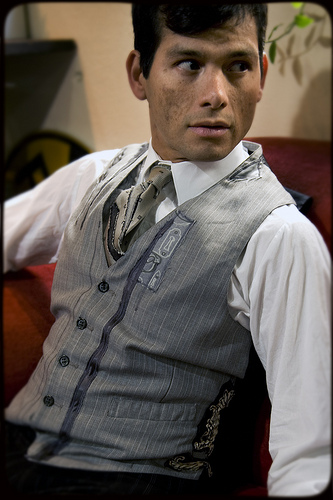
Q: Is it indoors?
A: Yes, it is indoors.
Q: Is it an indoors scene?
A: Yes, it is indoors.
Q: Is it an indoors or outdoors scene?
A: It is indoors.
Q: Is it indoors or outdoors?
A: It is indoors.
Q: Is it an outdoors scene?
A: No, it is indoors.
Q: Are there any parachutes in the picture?
A: No, there are no parachutes.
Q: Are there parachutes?
A: No, there are no parachutes.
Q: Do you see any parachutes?
A: No, there are no parachutes.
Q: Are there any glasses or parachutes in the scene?
A: No, there are no parachutes or glasses.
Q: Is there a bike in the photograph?
A: No, there are no bikes.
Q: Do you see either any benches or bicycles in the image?
A: No, there are no bicycles or benches.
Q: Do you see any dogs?
A: No, there are no dogs.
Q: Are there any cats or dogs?
A: No, there are no dogs or cats.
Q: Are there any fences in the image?
A: No, there are no fences.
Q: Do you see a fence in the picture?
A: No, there are no fences.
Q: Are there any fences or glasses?
A: No, there are no fences or glasses.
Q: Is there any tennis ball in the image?
A: No, there are no tennis balls.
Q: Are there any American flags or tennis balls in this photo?
A: No, there are no tennis balls or American flags.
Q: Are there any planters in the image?
A: No, there are no planters.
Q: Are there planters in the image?
A: No, there are no planters.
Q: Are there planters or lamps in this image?
A: No, there are no planters or lamps.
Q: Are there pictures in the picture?
A: No, there are no pictures.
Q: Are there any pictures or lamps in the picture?
A: No, there are no pictures or lamps.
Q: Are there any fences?
A: No, there are no fences.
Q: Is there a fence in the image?
A: No, there are no fences.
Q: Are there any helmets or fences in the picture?
A: No, there are no fences or helmets.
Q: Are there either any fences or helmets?
A: No, there are no fences or helmets.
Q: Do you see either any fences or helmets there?
A: No, there are no fences or helmets.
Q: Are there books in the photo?
A: No, there are no books.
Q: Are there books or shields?
A: No, there are no books or shields.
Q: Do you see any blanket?
A: No, there are no blankets.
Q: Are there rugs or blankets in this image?
A: No, there are no blankets or rugs.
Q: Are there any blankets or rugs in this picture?
A: No, there are no blankets or rugs.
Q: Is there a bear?
A: No, there are no bears.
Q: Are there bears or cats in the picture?
A: No, there are no bears or cats.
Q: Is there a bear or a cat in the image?
A: No, there are no bears or cats.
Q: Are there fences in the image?
A: No, there are no fences.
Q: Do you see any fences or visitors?
A: No, there are no fences or visitors.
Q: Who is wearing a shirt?
A: The man is wearing a shirt.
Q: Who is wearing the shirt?
A: The man is wearing a shirt.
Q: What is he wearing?
A: The man is wearing a shirt.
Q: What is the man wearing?
A: The man is wearing a shirt.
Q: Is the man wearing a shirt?
A: Yes, the man is wearing a shirt.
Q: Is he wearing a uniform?
A: No, the man is wearing a shirt.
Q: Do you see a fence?
A: No, there are no fences.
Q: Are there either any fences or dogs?
A: No, there are no fences or dogs.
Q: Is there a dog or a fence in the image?
A: No, there are no fences or dogs.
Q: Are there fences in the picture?
A: No, there are no fences.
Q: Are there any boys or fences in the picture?
A: No, there are no fences or boys.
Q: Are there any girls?
A: No, there are no girls.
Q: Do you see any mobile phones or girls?
A: No, there are no girls or mobile phones.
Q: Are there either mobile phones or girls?
A: No, there are no girls or mobile phones.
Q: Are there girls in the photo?
A: No, there are no girls.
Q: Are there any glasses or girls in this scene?
A: No, there are no girls or glasses.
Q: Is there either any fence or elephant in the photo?
A: No, there are no fences or elephants.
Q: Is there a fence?
A: No, there are no fences.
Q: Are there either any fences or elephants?
A: No, there are no fences or elephants.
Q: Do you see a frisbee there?
A: No, there are no frisbees.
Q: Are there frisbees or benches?
A: No, there are no frisbees or benches.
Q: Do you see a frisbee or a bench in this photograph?
A: No, there are no frisbees or benches.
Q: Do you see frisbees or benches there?
A: No, there are no frisbees or benches.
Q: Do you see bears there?
A: No, there are no bears.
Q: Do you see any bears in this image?
A: No, there are no bears.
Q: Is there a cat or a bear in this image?
A: No, there are no bears or cats.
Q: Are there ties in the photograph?
A: Yes, there is a tie.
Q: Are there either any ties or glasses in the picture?
A: Yes, there is a tie.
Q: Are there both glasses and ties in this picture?
A: No, there is a tie but no glasses.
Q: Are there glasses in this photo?
A: No, there are no glasses.